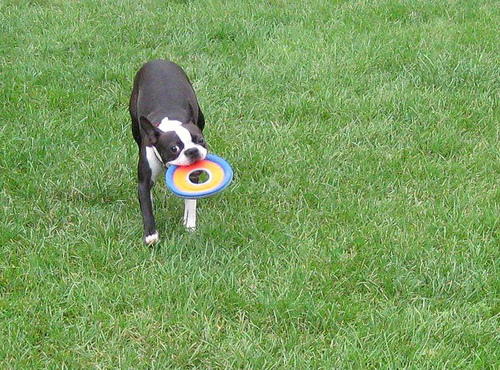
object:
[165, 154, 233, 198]
frisbee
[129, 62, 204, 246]
dog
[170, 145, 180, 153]
eye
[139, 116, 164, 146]
ear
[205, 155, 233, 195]
blue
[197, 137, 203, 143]
eye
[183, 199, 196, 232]
leg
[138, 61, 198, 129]
back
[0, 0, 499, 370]
grass